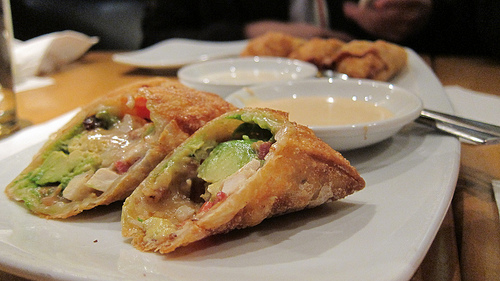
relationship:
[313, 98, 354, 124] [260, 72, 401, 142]
sauce in bowl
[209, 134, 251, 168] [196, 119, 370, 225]
avacado in shell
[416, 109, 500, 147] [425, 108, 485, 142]
handle has handle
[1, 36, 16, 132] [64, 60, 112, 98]
glass on table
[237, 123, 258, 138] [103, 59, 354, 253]
olive in food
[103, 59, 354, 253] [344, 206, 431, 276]
food on plate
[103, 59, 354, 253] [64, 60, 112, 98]
food on table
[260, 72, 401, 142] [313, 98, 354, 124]
bowl has sauce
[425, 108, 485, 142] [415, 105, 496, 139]
handle of utensil